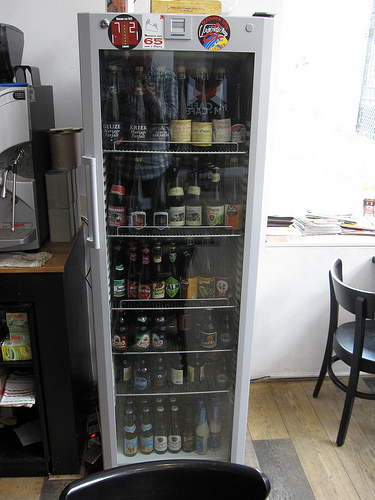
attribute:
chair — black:
[298, 266, 371, 426]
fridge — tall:
[83, 67, 306, 311]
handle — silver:
[90, 137, 118, 275]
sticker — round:
[194, 16, 265, 77]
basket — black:
[202, 425, 274, 492]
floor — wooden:
[243, 453, 322, 457]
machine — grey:
[3, 121, 78, 272]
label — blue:
[127, 420, 153, 460]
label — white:
[151, 420, 175, 458]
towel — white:
[154, 435, 192, 458]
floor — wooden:
[249, 394, 347, 479]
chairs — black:
[317, 276, 364, 378]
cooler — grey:
[60, 36, 354, 383]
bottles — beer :
[107, 67, 230, 454]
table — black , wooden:
[1, 239, 84, 477]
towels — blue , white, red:
[2, 363, 39, 410]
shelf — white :
[270, 204, 368, 247]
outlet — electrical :
[84, 402, 103, 468]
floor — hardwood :
[262, 389, 330, 494]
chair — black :
[313, 256, 368, 453]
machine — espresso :
[1, 114, 78, 261]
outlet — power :
[75, 401, 101, 469]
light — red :
[86, 423, 97, 440]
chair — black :
[62, 455, 278, 499]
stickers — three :
[104, 12, 234, 47]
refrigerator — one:
[69, 7, 251, 447]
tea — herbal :
[0, 304, 26, 359]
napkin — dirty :
[1, 246, 50, 269]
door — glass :
[95, 43, 245, 463]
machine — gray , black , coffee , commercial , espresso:
[5, 42, 79, 258]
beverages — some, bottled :
[110, 60, 229, 464]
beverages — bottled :
[110, 310, 234, 350]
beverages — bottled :
[114, 359, 231, 391]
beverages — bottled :
[117, 395, 226, 457]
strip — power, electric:
[77, 400, 105, 471]